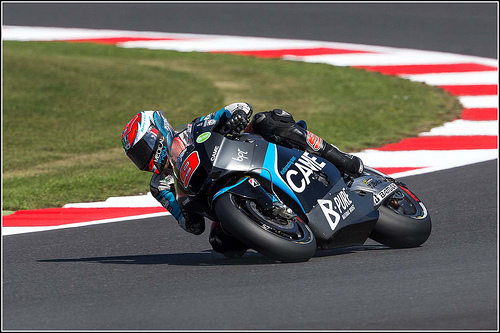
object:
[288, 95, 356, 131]
grass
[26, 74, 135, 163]
grass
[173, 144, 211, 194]
numbernine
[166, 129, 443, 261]
bike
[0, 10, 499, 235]
curve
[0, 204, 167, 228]
paint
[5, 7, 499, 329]
race track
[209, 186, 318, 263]
front wheel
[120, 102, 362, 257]
man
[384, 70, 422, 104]
ground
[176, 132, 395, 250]
frame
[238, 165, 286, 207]
cord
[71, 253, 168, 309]
grey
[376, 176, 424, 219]
strut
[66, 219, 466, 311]
racetrack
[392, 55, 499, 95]
line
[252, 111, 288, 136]
knee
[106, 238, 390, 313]
track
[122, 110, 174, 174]
helmet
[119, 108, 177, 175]
head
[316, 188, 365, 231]
writing